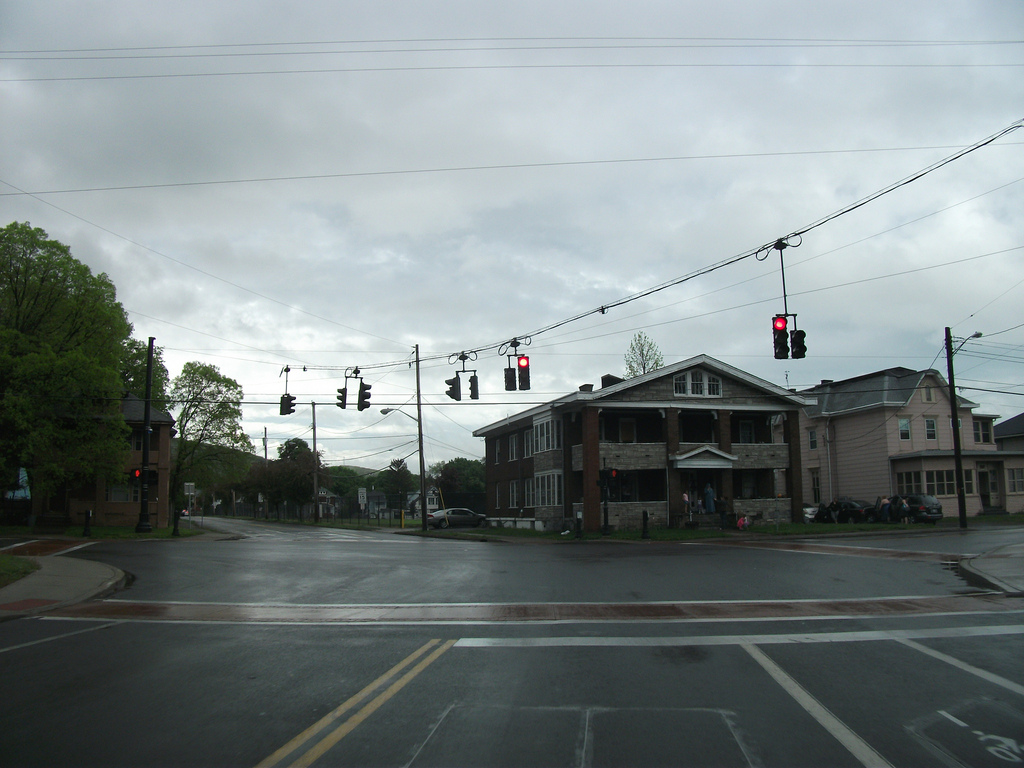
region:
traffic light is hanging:
[517, 351, 531, 390]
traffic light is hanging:
[769, 311, 786, 356]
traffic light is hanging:
[791, 327, 805, 356]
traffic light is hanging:
[507, 365, 515, 385]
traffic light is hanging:
[465, 374, 478, 403]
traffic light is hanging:
[444, 374, 461, 400]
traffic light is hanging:
[354, 382, 371, 409]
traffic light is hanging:
[338, 382, 351, 408]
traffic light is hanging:
[281, 395, 298, 415]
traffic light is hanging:
[279, 395, 287, 414]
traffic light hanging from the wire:
[512, 347, 535, 390]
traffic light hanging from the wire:
[764, 312, 787, 360]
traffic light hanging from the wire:
[786, 316, 809, 359]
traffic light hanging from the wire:
[502, 367, 521, 388]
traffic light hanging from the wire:
[462, 372, 488, 407]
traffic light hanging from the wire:
[443, 370, 462, 412]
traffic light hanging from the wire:
[357, 373, 377, 416]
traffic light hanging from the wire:
[281, 394, 300, 423]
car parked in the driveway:
[422, 492, 486, 530]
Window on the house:
[594, 402, 646, 438]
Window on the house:
[896, 416, 915, 432]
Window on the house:
[916, 414, 939, 438]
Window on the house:
[527, 411, 559, 449]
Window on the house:
[522, 465, 571, 503]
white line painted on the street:
[743, 614, 824, 766]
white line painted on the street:
[451, 622, 654, 662]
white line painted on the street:
[707, 619, 919, 657]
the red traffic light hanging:
[768, 309, 807, 363]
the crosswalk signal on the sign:
[130, 467, 143, 484]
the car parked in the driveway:
[427, 502, 486, 531]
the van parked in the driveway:
[863, 487, 944, 527]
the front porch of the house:
[667, 442, 740, 534]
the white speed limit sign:
[356, 487, 367, 507]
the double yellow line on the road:
[259, 633, 452, 766]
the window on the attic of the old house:
[670, 363, 731, 401]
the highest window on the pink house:
[919, 382, 935, 405]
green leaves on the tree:
[43, 323, 86, 358]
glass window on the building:
[923, 472, 939, 498]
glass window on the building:
[961, 460, 969, 493]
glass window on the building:
[895, 416, 914, 439]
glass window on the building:
[920, 415, 936, 436]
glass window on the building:
[909, 469, 920, 493]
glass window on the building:
[689, 365, 706, 395]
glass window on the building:
[669, 369, 688, 398]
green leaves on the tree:
[49, 314, 92, 372]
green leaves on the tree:
[64, 376, 128, 460]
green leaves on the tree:
[125, 370, 151, 399]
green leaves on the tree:
[181, 350, 224, 408]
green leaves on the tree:
[17, 235, 78, 311]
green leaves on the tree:
[5, 376, 86, 475]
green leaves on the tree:
[84, 265, 124, 358]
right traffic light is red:
[765, 303, 797, 365]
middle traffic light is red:
[512, 350, 535, 388]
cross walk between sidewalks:
[41, 580, 1022, 631]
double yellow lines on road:
[243, 625, 452, 761]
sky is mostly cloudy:
[3, 1, 1022, 472]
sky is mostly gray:
[3, 3, 1022, 466]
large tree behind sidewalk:
[2, 200, 154, 549]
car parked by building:
[424, 490, 478, 532]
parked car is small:
[420, 496, 490, 534]